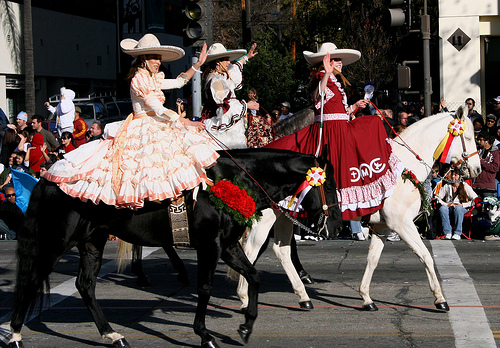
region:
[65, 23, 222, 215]
woman wearing pink ruffled dress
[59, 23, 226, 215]
woman wearing white hat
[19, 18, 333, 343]
woman riding a black horse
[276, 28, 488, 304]
woman riding a white horse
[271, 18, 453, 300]
woman wearing a red dress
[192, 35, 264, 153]
womanwearing a white dress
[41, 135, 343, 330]
black horse with red flowers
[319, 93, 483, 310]
white horse with yellow and red ribbon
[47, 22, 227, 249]
woman waving her hand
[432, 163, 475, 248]
woman sitting in a chair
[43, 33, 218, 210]
the woman wearing a dress with a lot of ruffles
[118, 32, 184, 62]
the hat on the woman's head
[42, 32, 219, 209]
the woman sitting on the horse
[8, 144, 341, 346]
the black horse under the woman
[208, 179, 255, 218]
the red flowers on the horse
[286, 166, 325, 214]
the ribbon on the horse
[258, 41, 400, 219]
the woman wearing a hat and a red dress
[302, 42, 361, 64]
the hat on the woman's head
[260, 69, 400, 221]
the red dress on the woman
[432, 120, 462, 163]
the ribbon on the horse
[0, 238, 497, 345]
A street below the horses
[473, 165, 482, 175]
The nose of the horse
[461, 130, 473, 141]
The right eye of the horse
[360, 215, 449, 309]
The front legs of the horse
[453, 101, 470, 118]
The eyes of the horse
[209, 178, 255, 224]
Flowers on the side of the hrose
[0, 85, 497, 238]
Spectators watching the parade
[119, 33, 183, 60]
The women is wearing a hat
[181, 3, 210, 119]
A traffic light by the horses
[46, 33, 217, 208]
A woman riding the horse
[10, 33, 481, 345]
three women on horses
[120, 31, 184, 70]
wide brimmed hat on head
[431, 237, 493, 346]
white line across road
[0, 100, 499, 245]
people along parade route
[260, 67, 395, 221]
red costume dress on rider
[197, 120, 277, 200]
horse reigns in hand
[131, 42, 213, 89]
waving hand of woman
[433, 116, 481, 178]
bridle on white horse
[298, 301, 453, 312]
hooves on horse feet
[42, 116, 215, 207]
ruffled two tone dress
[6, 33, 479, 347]
Women riding horses in a parade.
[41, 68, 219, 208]
A peach and white traditional Mexican dress.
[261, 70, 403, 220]
Red and white traditional Mexican dress.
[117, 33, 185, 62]
A tan sombrero.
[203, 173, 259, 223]
A red and green floral decoration.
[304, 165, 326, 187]
A flower decoration on the horse bridle.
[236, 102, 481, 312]
A white horse.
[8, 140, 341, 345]
A black horse with white above the back hooves.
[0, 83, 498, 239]
A crowd of people along the roadside.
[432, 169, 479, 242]
A woman sitting in a red chair.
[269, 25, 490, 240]
person on white horse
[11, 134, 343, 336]
black horse on street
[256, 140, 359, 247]
head of the horse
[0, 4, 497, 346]
View of downtown parade and spectators.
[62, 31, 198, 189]
Woman in ruffled pink and white gown and hat, astride horse.